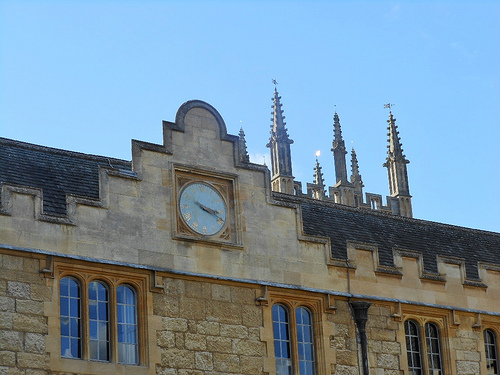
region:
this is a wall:
[254, 215, 312, 366]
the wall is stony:
[246, 210, 302, 283]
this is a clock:
[172, 168, 236, 244]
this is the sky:
[34, 11, 142, 98]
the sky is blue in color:
[2, 0, 136, 105]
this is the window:
[57, 278, 148, 363]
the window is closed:
[52, 275, 147, 362]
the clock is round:
[177, 185, 228, 230]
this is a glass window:
[57, 270, 90, 357]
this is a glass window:
[85, 275, 117, 362]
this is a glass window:
[114, 275, 145, 364]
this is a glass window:
[269, 301, 295, 374]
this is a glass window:
[292, 303, 324, 374]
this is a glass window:
[403, 313, 424, 373]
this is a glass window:
[422, 320, 447, 374]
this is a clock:
[182, 182, 233, 242]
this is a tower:
[265, 78, 300, 195]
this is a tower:
[332, 111, 358, 209]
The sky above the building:
[2, 2, 497, 226]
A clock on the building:
[179, 177, 227, 237]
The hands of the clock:
[196, 202, 221, 221]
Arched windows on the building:
[58, 272, 140, 362]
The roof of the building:
[1, 135, 498, 283]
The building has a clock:
[0, 77, 497, 373]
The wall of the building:
[1, 249, 498, 374]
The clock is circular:
[178, 177, 228, 235]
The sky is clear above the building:
[0, 1, 497, 235]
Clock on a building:
[160, 155, 252, 253]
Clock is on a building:
[160, 156, 250, 246]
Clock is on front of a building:
[166, 161, 242, 247]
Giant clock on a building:
[171, 161, 250, 248]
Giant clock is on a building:
[169, 155, 246, 249]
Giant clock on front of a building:
[165, 161, 250, 248]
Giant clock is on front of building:
[165, 163, 252, 245]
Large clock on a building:
[167, 166, 250, 253]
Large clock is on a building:
[169, 161, 245, 248]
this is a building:
[0, 81, 486, 362]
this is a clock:
[166, 156, 271, 279]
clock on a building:
[0, 102, 466, 372]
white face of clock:
[168, 170, 230, 230]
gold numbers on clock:
[176, 175, 225, 235]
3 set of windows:
[23, 250, 155, 366]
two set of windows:
[251, 285, 327, 374]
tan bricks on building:
[146, 268, 271, 373]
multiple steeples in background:
[248, 62, 433, 189]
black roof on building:
[15, 124, 480, 269]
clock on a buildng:
[163, 162, 242, 253]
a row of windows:
[43, 268, 148, 364]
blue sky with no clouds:
[1, 2, 499, 229]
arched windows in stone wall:
[50, 264, 150, 369]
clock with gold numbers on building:
[176, 178, 230, 238]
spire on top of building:
[266, 76, 296, 194]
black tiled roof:
[0, 136, 497, 281]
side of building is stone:
[3, 247, 498, 373]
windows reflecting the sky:
[264, 294, 315, 374]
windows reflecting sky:
[49, 263, 151, 368]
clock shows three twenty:
[175, 177, 232, 242]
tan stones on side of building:
[154, 277, 266, 374]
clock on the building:
[125, 108, 281, 274]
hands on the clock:
[155, 185, 225, 245]